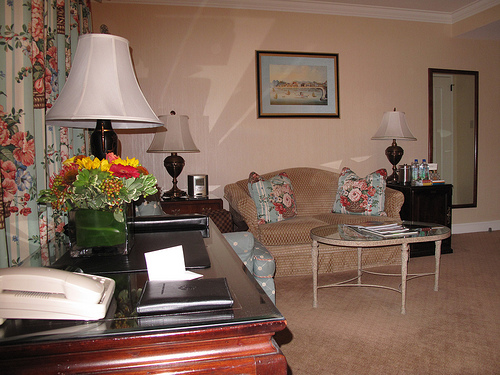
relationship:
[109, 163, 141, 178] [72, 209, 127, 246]
flower in vase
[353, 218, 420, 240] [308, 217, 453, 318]
magazines on coffee table